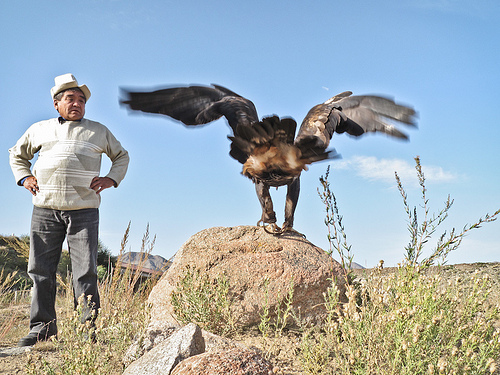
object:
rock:
[144, 225, 352, 332]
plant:
[316, 155, 500, 375]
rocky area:
[119, 225, 351, 375]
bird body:
[235, 128, 307, 182]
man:
[7, 74, 128, 347]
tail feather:
[244, 115, 312, 186]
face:
[268, 163, 296, 182]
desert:
[0, 261, 500, 374]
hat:
[51, 73, 92, 104]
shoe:
[16, 325, 49, 347]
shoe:
[80, 328, 96, 344]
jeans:
[27, 205, 100, 336]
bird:
[117, 82, 419, 239]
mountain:
[341, 262, 365, 271]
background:
[0, 25, 498, 268]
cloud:
[332, 148, 456, 194]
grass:
[317, 155, 500, 375]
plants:
[171, 265, 282, 340]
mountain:
[116, 251, 173, 274]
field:
[0, 235, 499, 375]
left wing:
[118, 82, 259, 137]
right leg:
[284, 177, 300, 224]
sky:
[0, 0, 500, 270]